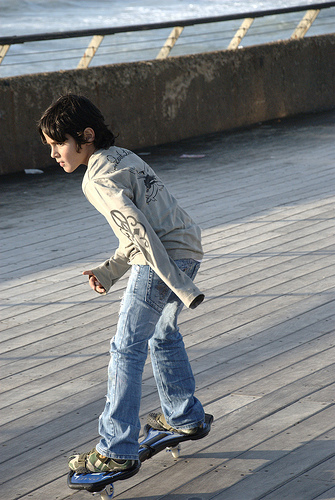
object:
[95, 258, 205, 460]
jeans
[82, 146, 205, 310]
sweater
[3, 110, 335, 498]
floor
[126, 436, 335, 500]
shadow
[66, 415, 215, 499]
skateboard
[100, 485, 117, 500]
wheels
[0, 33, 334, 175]
wall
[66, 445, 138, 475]
shoes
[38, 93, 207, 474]
boy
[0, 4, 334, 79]
surf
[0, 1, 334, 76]
railing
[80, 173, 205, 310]
sleeve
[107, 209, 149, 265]
design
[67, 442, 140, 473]
left foot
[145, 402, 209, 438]
right foot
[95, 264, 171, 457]
left leg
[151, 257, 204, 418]
right leg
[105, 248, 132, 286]
right arm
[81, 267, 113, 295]
right hand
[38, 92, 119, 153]
hair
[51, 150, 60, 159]
nose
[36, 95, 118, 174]
head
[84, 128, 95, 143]
left ear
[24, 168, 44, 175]
paper